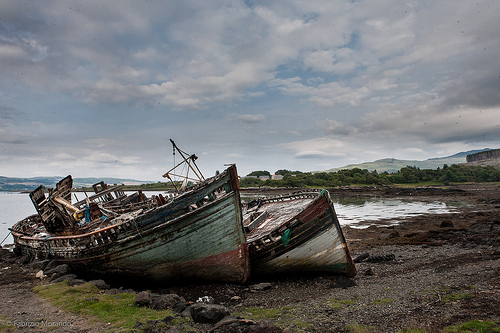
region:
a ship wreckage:
[119, 206, 248, 319]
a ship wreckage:
[209, 211, 288, 328]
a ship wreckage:
[182, 190, 322, 320]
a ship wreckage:
[180, 110, 355, 322]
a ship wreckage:
[176, 136, 282, 271]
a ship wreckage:
[171, 164, 253, 324]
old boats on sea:
[81, 142, 373, 302]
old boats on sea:
[140, 190, 418, 312]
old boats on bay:
[39, 119, 377, 321]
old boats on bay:
[54, 89, 244, 295]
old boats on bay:
[151, 140, 318, 302]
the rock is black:
[207, 308, 216, 312]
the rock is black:
[206, 308, 216, 323]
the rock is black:
[200, 300, 208, 317]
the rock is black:
[203, 308, 213, 318]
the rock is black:
[202, 308, 209, 313]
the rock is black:
[204, 309, 206, 314]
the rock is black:
[199, 305, 209, 312]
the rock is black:
[199, 309, 208, 316]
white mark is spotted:
[33, 265, 45, 290]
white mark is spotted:
[33, 269, 53, 282]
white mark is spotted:
[35, 268, 44, 278]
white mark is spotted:
[27, 266, 48, 285]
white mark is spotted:
[31, 265, 61, 287]